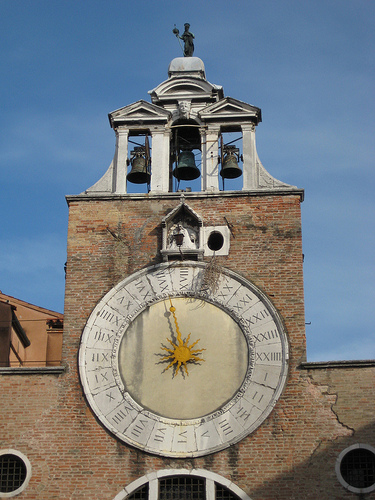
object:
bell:
[125, 146, 151, 184]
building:
[0, 21, 374, 498]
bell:
[171, 145, 201, 181]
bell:
[217, 144, 243, 180]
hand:
[166, 294, 184, 347]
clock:
[77, 259, 292, 459]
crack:
[307, 369, 355, 464]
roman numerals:
[217, 417, 233, 438]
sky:
[0, 0, 374, 362]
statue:
[171, 21, 196, 57]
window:
[334, 443, 374, 495]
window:
[0, 448, 32, 496]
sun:
[155, 330, 207, 380]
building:
[0, 291, 64, 367]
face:
[178, 101, 192, 114]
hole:
[206, 231, 223, 252]